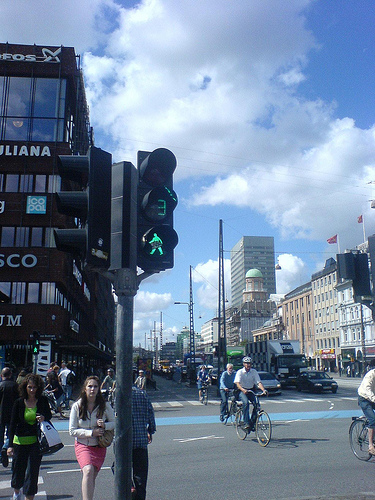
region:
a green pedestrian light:
[139, 221, 178, 267]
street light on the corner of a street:
[54, 142, 177, 274]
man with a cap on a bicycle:
[233, 356, 272, 446]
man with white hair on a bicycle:
[218, 362, 241, 424]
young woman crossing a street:
[69, 374, 115, 496]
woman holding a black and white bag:
[34, 411, 64, 456]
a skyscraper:
[231, 235, 277, 306]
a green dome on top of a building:
[246, 266, 263, 276]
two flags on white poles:
[325, 212, 367, 253]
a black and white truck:
[247, 339, 308, 386]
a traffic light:
[133, 151, 187, 273]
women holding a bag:
[37, 424, 63, 450]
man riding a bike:
[234, 366, 275, 440]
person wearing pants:
[133, 451, 151, 497]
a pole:
[109, 294, 141, 369]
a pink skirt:
[72, 444, 108, 469]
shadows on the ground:
[53, 454, 71, 469]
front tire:
[255, 415, 278, 442]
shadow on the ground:
[286, 427, 325, 451]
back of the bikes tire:
[342, 415, 367, 455]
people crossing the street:
[13, 367, 111, 485]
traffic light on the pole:
[122, 143, 187, 279]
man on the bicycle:
[223, 350, 278, 439]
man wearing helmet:
[235, 355, 254, 368]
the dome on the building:
[242, 263, 266, 279]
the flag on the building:
[317, 228, 344, 247]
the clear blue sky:
[322, 55, 364, 92]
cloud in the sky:
[162, 10, 225, 105]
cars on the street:
[218, 328, 329, 396]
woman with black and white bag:
[12, 396, 61, 463]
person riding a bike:
[230, 356, 279, 450]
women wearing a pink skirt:
[74, 443, 112, 467]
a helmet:
[243, 356, 256, 366]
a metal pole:
[110, 291, 143, 370]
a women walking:
[12, 369, 60, 485]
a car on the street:
[304, 366, 338, 390]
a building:
[2, 124, 70, 332]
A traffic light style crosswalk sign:
[53, 146, 178, 499]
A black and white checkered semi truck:
[244, 340, 307, 387]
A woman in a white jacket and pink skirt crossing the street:
[68, 374, 115, 498]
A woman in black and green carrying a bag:
[5, 372, 65, 498]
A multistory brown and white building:
[0, 43, 116, 385]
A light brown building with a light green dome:
[220, 268, 278, 344]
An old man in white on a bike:
[231, 356, 272, 444]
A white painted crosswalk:
[0, 423, 52, 498]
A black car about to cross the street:
[294, 370, 338, 392]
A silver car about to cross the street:
[256, 369, 282, 395]